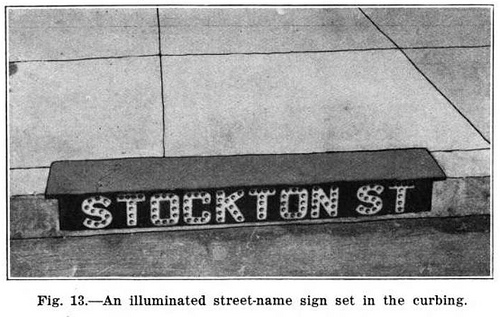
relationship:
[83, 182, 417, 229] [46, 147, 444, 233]
word on plate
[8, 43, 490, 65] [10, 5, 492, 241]
line on sidewalk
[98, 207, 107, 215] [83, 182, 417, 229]
dot on word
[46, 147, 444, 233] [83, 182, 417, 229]
plate has word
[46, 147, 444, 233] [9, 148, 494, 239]
plate on curb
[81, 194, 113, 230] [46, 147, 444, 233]
letter s on plate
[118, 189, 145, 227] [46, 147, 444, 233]
letter t on plate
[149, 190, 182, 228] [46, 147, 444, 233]
letter o on plate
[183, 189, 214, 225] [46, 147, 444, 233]
letter c on plate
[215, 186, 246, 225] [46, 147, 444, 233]
letter k on plate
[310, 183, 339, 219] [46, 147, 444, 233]
letter n on plate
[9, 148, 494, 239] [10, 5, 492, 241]
curb on sidewalk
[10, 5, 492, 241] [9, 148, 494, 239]
sidewalk has curb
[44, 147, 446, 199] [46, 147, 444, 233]
top of plate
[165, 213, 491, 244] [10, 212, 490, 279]
stain on road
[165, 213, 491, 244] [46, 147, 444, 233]
stain below plate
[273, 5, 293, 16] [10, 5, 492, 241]
spot on sidewalk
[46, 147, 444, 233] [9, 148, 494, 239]
plate in curb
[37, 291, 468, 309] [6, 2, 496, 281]
caption under photo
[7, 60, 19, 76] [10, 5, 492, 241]
stain on sidewalk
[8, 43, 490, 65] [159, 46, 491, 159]
line next to square